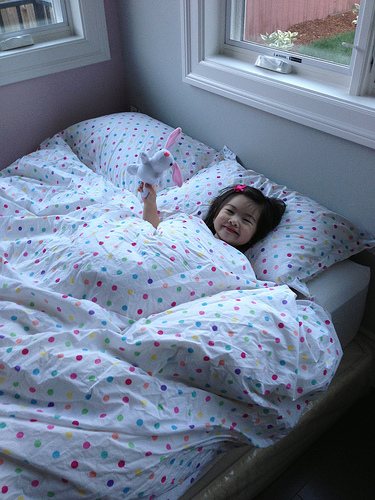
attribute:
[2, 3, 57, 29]
rail — black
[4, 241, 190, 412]
cover — white, dotted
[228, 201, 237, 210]
eyebrow — dark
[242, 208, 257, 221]
eyebrow — dark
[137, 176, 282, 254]
girl — little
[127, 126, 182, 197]
bunny — stuffed, animal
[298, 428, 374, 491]
floor — tiled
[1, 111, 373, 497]
polka dots — pink, purple, green, blue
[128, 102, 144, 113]
outlet — wall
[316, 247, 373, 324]
sheet — white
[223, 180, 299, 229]
hair — large, dark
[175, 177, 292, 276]
kid — little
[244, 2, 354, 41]
fence — brown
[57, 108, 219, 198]
pillow — white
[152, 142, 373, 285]
pollow — colorful, dot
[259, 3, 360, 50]
plants — few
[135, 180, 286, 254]
child — happy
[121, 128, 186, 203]
rabbit — white and pink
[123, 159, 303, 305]
girl — young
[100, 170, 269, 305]
girl — smiling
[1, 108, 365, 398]
mattress — white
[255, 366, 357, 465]
mattress — white